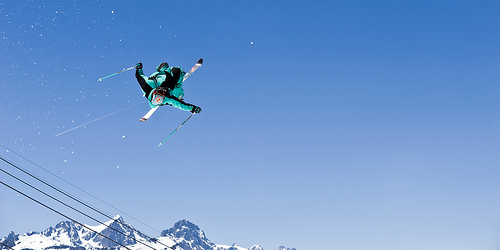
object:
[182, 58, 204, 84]
ski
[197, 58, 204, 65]
black tip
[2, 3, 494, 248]
sky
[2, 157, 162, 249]
power lines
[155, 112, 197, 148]
pole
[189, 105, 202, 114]
hand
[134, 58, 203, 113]
person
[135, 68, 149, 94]
arm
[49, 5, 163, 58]
snow scattered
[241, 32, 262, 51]
snow scattered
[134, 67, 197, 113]
snow suit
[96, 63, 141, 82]
pole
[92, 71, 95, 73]
flecks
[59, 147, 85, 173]
flecks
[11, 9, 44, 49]
flecks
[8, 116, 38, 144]
flecks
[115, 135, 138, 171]
flecks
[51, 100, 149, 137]
power poles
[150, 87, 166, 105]
helmet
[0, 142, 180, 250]
cables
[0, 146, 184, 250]
wires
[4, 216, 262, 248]
mountain range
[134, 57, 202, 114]
man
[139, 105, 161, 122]
ski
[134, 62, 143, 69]
hand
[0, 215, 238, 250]
mountain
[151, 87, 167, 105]
hat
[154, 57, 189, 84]
feet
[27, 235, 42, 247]
snow